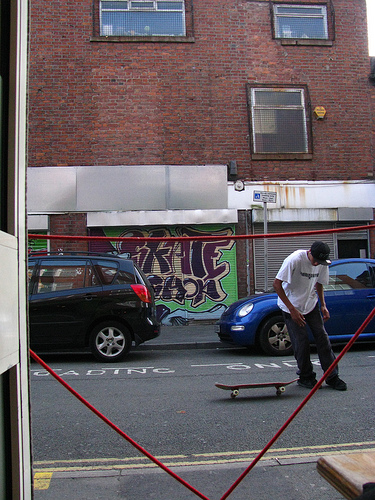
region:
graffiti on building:
[132, 222, 270, 316]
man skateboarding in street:
[213, 241, 374, 402]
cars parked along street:
[48, 247, 361, 361]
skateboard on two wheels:
[207, 364, 303, 406]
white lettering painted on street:
[34, 351, 344, 391]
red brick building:
[72, 59, 220, 149]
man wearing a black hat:
[288, 238, 339, 279]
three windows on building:
[98, 6, 339, 153]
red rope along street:
[49, 212, 364, 491]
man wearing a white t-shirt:
[264, 232, 353, 323]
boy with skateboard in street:
[214, 230, 355, 410]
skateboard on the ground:
[208, 373, 306, 403]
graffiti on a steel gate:
[106, 228, 244, 318]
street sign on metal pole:
[249, 186, 282, 292]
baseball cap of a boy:
[309, 240, 339, 265]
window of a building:
[239, 73, 317, 170]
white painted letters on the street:
[36, 357, 303, 382]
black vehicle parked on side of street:
[24, 246, 168, 367]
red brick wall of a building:
[36, 47, 238, 152]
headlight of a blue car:
[236, 298, 256, 322]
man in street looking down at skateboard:
[211, 231, 356, 407]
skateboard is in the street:
[204, 366, 300, 401]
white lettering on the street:
[42, 349, 314, 384]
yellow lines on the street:
[46, 441, 302, 483]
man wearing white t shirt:
[279, 249, 334, 322]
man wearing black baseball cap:
[298, 238, 336, 280]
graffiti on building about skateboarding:
[86, 208, 240, 318]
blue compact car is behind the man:
[217, 246, 372, 353]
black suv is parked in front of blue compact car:
[30, 241, 157, 361]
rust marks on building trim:
[248, 167, 341, 218]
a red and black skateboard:
[208, 377, 308, 398]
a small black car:
[28, 243, 167, 363]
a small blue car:
[198, 236, 371, 370]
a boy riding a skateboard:
[193, 223, 353, 406]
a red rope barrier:
[28, 212, 369, 494]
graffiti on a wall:
[80, 211, 251, 333]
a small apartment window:
[236, 76, 328, 168]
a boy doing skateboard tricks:
[177, 229, 363, 404]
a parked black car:
[31, 235, 171, 363]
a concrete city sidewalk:
[29, 440, 371, 498]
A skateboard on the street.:
[207, 373, 303, 398]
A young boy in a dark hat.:
[275, 242, 348, 280]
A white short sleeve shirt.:
[275, 243, 333, 319]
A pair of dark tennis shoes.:
[294, 370, 350, 392]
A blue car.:
[218, 248, 373, 349]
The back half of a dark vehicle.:
[28, 242, 167, 363]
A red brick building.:
[38, 12, 368, 285]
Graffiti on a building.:
[90, 224, 245, 319]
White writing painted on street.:
[35, 355, 324, 382]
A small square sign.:
[248, 186, 280, 205]